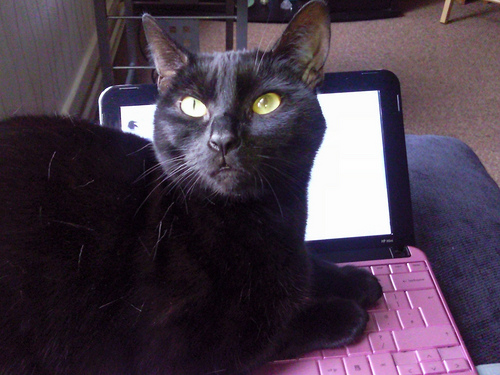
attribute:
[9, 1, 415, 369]
cat — black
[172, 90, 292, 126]
eyes — silver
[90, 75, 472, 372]
computer — black, on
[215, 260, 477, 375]
keyboard — pink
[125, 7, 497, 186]
floor — brown